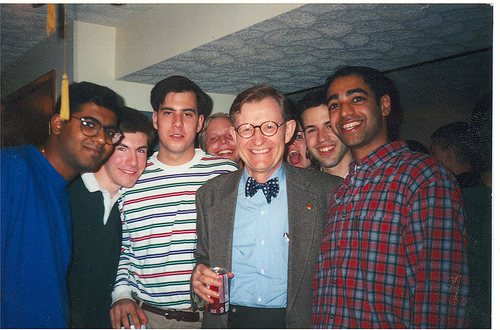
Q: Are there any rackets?
A: No, there are no rackets.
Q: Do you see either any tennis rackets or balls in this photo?
A: No, there are no tennis rackets or balls.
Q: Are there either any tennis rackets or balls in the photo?
A: No, there are no tennis rackets or balls.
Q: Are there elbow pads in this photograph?
A: No, there are no elbow pads.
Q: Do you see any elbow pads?
A: No, there are no elbow pads.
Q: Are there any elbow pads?
A: No, there are no elbow pads.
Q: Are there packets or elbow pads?
A: No, there are no elbow pads or packets.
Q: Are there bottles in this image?
A: No, there are no bottles.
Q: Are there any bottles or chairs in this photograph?
A: No, there are no bottles or chairs.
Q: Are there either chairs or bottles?
A: No, there are no bottles or chairs.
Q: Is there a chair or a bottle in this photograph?
A: No, there are no bottles or chairs.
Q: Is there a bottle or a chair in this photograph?
A: No, there are no bottles or chairs.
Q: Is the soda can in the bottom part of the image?
A: Yes, the soda can is in the bottom of the image.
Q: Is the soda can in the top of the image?
A: No, the soda can is in the bottom of the image.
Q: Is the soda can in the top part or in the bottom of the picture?
A: The soda can is in the bottom of the image.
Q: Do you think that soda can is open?
A: Yes, the soda can is open.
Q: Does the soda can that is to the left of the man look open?
A: Yes, the soda can is open.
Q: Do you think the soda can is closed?
A: No, the soda can is open.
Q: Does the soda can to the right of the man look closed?
A: No, the soda can is open.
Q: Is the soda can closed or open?
A: The soda can is open.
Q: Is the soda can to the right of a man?
A: Yes, the soda can is to the right of a man.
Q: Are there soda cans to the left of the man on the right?
A: Yes, there is a soda can to the left of the man.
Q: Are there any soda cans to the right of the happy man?
A: No, the soda can is to the left of the man.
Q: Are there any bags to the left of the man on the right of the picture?
A: No, there is a soda can to the left of the man.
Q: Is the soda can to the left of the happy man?
A: Yes, the soda can is to the left of the man.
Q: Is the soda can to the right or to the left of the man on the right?
A: The soda can is to the left of the man.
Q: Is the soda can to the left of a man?
A: No, the soda can is to the right of a man.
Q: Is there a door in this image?
A: Yes, there is a door.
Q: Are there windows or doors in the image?
A: Yes, there is a door.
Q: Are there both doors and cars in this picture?
A: No, there is a door but no cars.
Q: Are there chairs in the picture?
A: No, there are no chairs.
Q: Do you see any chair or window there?
A: No, there are no chairs or windows.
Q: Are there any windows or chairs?
A: No, there are no chairs or windows.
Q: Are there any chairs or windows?
A: No, there are no chairs or windows.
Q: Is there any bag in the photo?
A: No, there are no bags.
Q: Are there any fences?
A: No, there are no fences.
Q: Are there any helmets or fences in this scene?
A: No, there are no fences or helmets.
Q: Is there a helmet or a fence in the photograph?
A: No, there are no fences or helmets.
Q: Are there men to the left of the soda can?
A: Yes, there is a man to the left of the soda can.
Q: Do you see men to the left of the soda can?
A: Yes, there is a man to the left of the soda can.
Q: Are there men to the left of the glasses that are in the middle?
A: Yes, there is a man to the left of the glasses.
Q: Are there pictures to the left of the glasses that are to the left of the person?
A: No, there is a man to the left of the glasses.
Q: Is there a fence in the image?
A: No, there are no fences.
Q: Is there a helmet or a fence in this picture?
A: No, there are no fences or helmets.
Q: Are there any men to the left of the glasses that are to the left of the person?
A: Yes, there is a man to the left of the glasses.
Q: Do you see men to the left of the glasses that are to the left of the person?
A: Yes, there is a man to the left of the glasses.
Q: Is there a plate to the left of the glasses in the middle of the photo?
A: No, there is a man to the left of the glasses.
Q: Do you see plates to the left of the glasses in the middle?
A: No, there is a man to the left of the glasses.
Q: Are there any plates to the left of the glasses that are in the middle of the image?
A: No, there is a man to the left of the glasses.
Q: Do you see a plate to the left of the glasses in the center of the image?
A: No, there is a man to the left of the glasses.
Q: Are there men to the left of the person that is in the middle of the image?
A: Yes, there is a man to the left of the person.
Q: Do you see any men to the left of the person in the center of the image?
A: Yes, there is a man to the left of the person.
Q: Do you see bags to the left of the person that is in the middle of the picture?
A: No, there is a man to the left of the person.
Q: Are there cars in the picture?
A: No, there are no cars.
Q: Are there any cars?
A: No, there are no cars.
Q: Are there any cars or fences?
A: No, there are no cars or fences.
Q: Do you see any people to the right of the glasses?
A: Yes, there is a person to the right of the glasses.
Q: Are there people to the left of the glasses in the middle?
A: No, the person is to the right of the glasses.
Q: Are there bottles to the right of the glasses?
A: No, there is a person to the right of the glasses.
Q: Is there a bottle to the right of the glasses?
A: No, there is a person to the right of the glasses.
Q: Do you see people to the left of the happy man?
A: Yes, there is a person to the left of the man.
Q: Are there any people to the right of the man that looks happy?
A: No, the person is to the left of the man.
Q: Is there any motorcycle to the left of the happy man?
A: No, there is a person to the left of the man.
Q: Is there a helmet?
A: No, there are no helmets.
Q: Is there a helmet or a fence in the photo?
A: No, there are no helmets or fences.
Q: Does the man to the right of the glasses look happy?
A: Yes, the man is happy.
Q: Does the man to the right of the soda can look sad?
A: No, the man is happy.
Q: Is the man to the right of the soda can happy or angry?
A: The man is happy.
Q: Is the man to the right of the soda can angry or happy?
A: The man is happy.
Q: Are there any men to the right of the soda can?
A: Yes, there is a man to the right of the soda can.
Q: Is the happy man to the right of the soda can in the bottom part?
A: Yes, the man is to the right of the soda can.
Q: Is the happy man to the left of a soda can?
A: No, the man is to the right of a soda can.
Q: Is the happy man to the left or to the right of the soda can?
A: The man is to the right of the soda can.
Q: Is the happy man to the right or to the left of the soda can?
A: The man is to the right of the soda can.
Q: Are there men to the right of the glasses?
A: Yes, there is a man to the right of the glasses.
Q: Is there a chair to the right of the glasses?
A: No, there is a man to the right of the glasses.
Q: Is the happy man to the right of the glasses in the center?
A: Yes, the man is to the right of the glasses.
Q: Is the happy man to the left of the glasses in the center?
A: No, the man is to the right of the glasses.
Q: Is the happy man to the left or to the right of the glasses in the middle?
A: The man is to the right of the glasses.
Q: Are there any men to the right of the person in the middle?
A: Yes, there is a man to the right of the person.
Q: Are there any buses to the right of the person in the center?
A: No, there is a man to the right of the person.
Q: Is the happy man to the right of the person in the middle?
A: Yes, the man is to the right of the person.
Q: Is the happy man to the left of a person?
A: No, the man is to the right of a person.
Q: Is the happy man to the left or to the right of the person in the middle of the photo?
A: The man is to the right of the person.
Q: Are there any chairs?
A: No, there are no chairs.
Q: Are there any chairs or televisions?
A: No, there are no chairs or televisions.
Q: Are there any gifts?
A: No, there are no gifts.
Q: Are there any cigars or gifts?
A: No, there are no gifts or cigars.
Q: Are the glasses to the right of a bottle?
A: No, the glasses are to the right of a man.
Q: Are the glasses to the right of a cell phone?
A: No, the glasses are to the right of a man.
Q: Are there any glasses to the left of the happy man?
A: Yes, there are glasses to the left of the man.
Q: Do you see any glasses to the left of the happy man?
A: Yes, there are glasses to the left of the man.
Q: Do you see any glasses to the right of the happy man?
A: No, the glasses are to the left of the man.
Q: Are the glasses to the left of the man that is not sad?
A: Yes, the glasses are to the left of the man.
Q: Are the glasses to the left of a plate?
A: No, the glasses are to the left of the man.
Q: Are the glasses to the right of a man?
A: No, the glasses are to the left of a man.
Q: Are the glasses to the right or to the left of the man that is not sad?
A: The glasses are to the left of the man.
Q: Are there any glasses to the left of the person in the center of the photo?
A: Yes, there are glasses to the left of the person.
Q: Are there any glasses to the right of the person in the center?
A: No, the glasses are to the left of the person.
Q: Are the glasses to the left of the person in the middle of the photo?
A: Yes, the glasses are to the left of the person.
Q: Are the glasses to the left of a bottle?
A: No, the glasses are to the left of the person.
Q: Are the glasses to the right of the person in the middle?
A: No, the glasses are to the left of the person.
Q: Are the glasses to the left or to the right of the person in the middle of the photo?
A: The glasses are to the left of the person.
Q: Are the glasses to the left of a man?
A: No, the glasses are to the right of a man.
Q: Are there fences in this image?
A: No, there are no fences.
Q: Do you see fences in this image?
A: No, there are no fences.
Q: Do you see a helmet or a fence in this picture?
A: No, there are no fences or helmets.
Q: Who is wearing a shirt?
A: The man is wearing a shirt.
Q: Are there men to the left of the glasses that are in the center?
A: Yes, there is a man to the left of the glasses.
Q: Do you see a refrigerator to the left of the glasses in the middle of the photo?
A: No, there is a man to the left of the glasses.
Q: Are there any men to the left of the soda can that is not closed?
A: Yes, there is a man to the left of the soda can.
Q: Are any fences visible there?
A: No, there are no fences.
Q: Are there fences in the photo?
A: No, there are no fences.